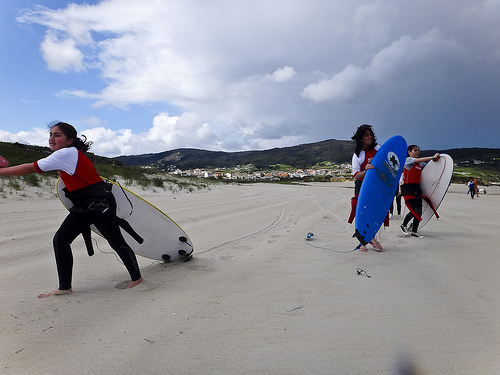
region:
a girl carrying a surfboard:
[342, 98, 397, 261]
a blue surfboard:
[346, 133, 409, 242]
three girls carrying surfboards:
[27, 95, 458, 312]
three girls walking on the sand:
[23, 103, 467, 320]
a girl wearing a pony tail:
[19, 115, 114, 202]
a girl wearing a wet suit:
[13, 125, 166, 306]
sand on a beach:
[251, 255, 473, 373]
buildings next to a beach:
[156, 152, 338, 205]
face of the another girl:
[343, 103, 394, 162]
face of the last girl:
[405, 138, 432, 164]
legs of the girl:
[31, 229, 138, 275]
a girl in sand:
[21, 103, 193, 314]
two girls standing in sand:
[315, 94, 460, 282]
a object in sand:
[287, 201, 328, 255]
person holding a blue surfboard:
[340, 122, 406, 249]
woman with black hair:
[348, 120, 388, 156]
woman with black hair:
[38, 121, 93, 153]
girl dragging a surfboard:
[24, 156, 207, 277]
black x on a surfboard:
[380, 143, 407, 172]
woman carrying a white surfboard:
[417, 149, 457, 231]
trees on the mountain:
[196, 139, 333, 164]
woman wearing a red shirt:
[41, 148, 98, 195]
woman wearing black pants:
[43, 203, 145, 292]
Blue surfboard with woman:
[343, 134, 409, 240]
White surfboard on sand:
[51, 173, 195, 267]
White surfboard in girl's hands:
[415, 152, 451, 232]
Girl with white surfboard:
[3, 124, 193, 296]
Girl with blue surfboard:
[343, 115, 407, 248]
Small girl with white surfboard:
[403, 145, 455, 232]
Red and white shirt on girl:
[27, 146, 103, 188]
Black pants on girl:
[52, 206, 143, 283]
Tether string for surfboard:
[302, 228, 361, 253]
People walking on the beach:
[462, 177, 480, 198]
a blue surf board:
[346, 135, 412, 246]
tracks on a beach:
[206, 181, 328, 279]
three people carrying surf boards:
[3, 126, 472, 297]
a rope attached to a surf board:
[297, 226, 368, 253]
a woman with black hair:
[354, 118, 379, 157]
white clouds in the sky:
[92, 73, 301, 116]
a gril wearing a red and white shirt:
[12, 121, 106, 197]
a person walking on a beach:
[467, 167, 483, 202]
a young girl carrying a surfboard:
[402, 120, 459, 244]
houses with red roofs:
[249, 163, 322, 184]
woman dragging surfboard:
[13, 110, 203, 289]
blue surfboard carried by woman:
[367, 131, 407, 239]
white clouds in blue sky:
[136, 87, 166, 109]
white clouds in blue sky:
[222, 77, 268, 109]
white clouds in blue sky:
[359, 33, 407, 65]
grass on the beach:
[121, 161, 140, 173]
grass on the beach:
[453, 155, 465, 167]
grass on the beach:
[88, 148, 110, 170]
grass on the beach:
[120, 161, 169, 188]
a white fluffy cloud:
[166, 6, 221, 74]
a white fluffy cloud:
[228, 15, 264, 60]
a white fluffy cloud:
[272, 26, 388, 126]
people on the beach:
[26, 81, 452, 276]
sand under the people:
[186, 279, 311, 340]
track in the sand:
[216, 197, 302, 256]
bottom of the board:
[324, 193, 406, 263]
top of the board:
[378, 124, 415, 176]